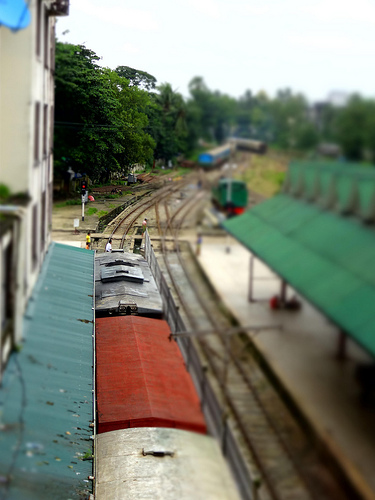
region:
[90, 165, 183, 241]
a set of train tacks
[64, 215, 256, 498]
a train on the tracks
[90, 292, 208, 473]
a red train car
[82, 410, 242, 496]
a tan train car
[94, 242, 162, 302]
roof hatch on train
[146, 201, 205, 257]
split of train tracks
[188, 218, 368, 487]
train platform next to tracks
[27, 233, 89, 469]
the roof is green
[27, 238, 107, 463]
the roof is green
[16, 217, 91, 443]
the roof is green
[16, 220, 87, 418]
the roof is green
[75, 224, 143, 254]
people in the train tracks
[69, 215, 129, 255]
people in the train tracks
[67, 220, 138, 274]
people in the train tracks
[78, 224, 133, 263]
people in the train tracks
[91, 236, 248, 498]
a row of trains on a track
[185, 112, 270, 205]
trains going on a track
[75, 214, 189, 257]
bystanders by a train station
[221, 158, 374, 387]
the cover of a small pavilion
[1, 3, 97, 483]
a large building with white paint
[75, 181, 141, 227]
a small pole on the side of tracks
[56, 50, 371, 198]
a forest surrounding a train station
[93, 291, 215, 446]
rust colored train car roof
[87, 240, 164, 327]
dark brown car roof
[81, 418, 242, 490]
light tan train car roof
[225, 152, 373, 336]
emerald green roof to right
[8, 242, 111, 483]
teal green roof to left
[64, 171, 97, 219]
metal crossing light near track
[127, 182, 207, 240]
train tracks for trains in yard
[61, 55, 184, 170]
dark green trees by tracks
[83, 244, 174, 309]
section of a train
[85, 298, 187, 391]
section of a train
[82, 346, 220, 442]
section of a train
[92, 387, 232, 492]
section of a train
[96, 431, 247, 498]
section of a train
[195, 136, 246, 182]
section of a train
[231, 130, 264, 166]
section of a train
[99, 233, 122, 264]
This is a person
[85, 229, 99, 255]
This is a person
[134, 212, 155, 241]
This is a person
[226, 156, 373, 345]
green shelter over the platform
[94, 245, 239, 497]
train cars in the station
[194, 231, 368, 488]
platform next to train tracks